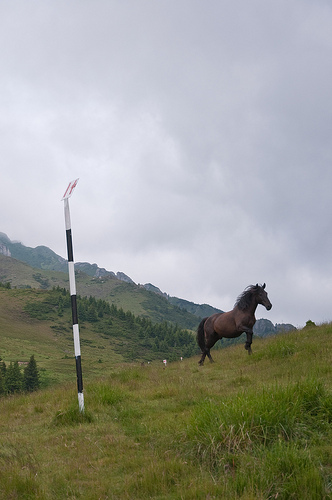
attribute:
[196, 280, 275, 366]
horse — walking, black, dark brown, brown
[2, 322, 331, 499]
hill — grassy, green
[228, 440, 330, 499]
grass — green, tall, long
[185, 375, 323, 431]
grass — green, tall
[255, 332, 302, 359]
grass — green, tall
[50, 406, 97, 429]
grass — green, tall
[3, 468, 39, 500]
grass — green, tall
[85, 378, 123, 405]
grass — green, tall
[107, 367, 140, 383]
grass — green, tall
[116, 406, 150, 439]
grass — green, tall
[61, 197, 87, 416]
pole — black, white, striped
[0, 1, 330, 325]
sky — cloudy, dark, overcast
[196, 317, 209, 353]
tail — long, bushy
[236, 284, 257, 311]
mane — dark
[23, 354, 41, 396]
tree — green